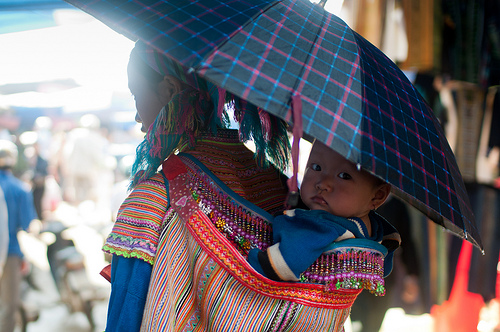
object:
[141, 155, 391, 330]
pouch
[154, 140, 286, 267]
back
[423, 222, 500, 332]
object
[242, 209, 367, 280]
top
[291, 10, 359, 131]
stripe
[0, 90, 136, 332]
people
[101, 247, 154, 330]
shirt sleeve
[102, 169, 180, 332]
left arm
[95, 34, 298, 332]
lady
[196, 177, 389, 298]
rows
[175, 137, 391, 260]
edge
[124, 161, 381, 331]
carrier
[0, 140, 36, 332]
person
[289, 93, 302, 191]
ribbon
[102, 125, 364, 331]
shirt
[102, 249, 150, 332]
blue sleeve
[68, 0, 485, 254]
umbrella`s top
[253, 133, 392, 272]
baby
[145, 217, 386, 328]
bag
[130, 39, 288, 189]
scarf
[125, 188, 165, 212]
stripes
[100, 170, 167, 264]
sleeve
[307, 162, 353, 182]
eyes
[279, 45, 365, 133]
checkers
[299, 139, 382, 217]
baby's cheek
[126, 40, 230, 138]
head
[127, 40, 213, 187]
bandana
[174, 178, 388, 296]
beading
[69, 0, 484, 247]
umbrella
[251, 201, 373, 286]
outfit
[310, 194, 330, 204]
lips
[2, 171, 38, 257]
shirt